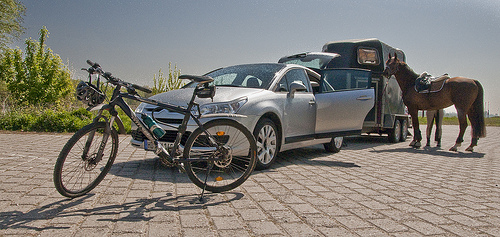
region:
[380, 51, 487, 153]
horse next to car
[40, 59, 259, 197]
bicycle in front of car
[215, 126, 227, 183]
orange lights on bicycle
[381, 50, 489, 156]
the horse is brown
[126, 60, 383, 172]
the car is silver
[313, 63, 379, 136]
car door is open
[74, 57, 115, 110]
helmet hanging from bike handle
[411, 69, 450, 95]
brown saddle on the horse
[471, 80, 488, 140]
horse's tail hair is brown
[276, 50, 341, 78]
car trunk is open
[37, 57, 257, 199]
Bicycle parked on brick pavement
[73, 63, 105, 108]
Bike helmet hanging from handlebars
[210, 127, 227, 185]
Reflectors on bicycle wheel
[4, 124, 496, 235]
Brick paved road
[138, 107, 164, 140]
Water bottle attached to bicycle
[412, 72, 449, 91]
Saddle on horse's back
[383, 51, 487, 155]
Saddled horse on brick pavement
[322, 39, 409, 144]
Trailer for carrying horses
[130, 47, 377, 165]
Silver car on brick pavement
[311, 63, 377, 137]
Open rear car door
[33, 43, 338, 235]
a bike on the road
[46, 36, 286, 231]
a bicycle on the road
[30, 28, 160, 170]
a helmet hangin gon the bike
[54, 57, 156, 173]
a helmet hanging on the bicycle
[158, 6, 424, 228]
a car parked on the road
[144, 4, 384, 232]
a car parked on the street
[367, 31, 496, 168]
a horse on the road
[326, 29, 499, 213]
a brown horse on the road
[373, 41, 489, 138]
a saddle on a horse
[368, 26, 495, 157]
a saddle on a brown horse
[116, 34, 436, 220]
the car is silver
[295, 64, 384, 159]
car's door is open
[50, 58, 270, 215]
The black bike.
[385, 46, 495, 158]
The brown horse on the right.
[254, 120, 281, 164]
The left front wheel on the car.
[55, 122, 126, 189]
The front bike tire.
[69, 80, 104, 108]
The helmet on the bike.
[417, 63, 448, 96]
The saddle on the horse.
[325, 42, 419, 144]
The trailer behind the car.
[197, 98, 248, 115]
Left front light.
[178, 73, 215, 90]
The bike seat.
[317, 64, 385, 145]
The left back car door.